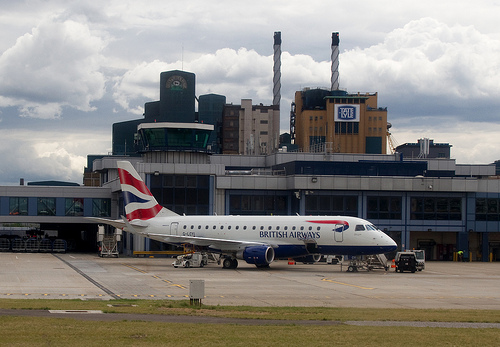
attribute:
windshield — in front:
[355, 217, 378, 230]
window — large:
[61, 194, 86, 218]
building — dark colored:
[99, 52, 442, 179]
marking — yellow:
[117, 259, 230, 309]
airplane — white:
[94, 140, 442, 271]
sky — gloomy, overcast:
[56, 53, 114, 109]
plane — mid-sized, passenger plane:
[81, 153, 399, 270]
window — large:
[361, 193, 406, 223]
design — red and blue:
[118, 167, 155, 225]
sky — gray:
[3, 2, 498, 174]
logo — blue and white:
[333, 104, 361, 121]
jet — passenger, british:
[101, 158, 416, 281]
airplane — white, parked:
[86, 158, 398, 268]